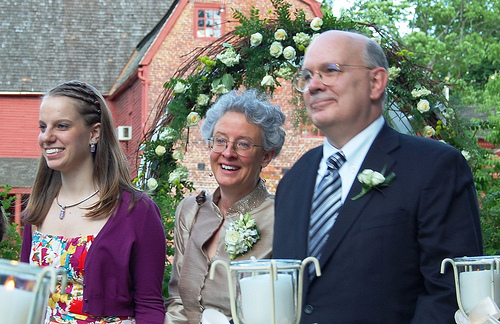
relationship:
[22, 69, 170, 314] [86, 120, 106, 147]
person has ear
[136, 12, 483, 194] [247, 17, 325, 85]
arch has flowers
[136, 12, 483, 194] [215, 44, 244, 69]
arch has flowers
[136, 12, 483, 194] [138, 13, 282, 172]
arch has wicker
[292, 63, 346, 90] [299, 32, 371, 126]
glasses are on face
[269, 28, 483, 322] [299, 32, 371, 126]
man has face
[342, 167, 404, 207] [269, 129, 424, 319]
flower on suit jacket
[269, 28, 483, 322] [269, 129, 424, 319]
man wearing suit jacket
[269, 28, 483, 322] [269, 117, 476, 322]
man wearing suit jacket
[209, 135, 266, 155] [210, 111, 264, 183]
glasses are on face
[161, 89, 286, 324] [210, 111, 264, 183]
person has face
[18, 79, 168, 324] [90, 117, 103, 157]
person has ear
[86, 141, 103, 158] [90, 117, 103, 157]
earring in ear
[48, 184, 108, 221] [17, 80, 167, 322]
necklace on woman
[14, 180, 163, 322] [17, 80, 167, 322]
sweater on woman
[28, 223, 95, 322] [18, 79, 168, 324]
dress on person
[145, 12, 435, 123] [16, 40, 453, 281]
wreath behind people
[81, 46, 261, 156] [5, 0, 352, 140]
wall on building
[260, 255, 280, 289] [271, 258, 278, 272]
handle part has part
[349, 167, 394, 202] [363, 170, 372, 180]
flower has part